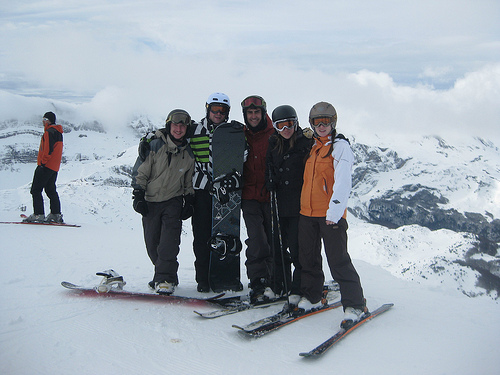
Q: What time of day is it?
A: Day time.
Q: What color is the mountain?
A: Gray and white.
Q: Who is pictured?
A: Snowboarders.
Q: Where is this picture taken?
A: Mountain top.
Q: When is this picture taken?
A: While boarding.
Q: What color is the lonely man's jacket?
A: Orange and black.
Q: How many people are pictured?
A: 6.